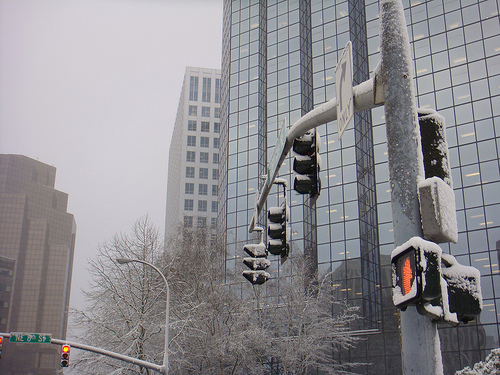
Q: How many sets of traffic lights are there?
A: There are three sets of traffic lights.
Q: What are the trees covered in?
A: The trees are covered in snow.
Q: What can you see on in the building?
A: The lights are on in the building.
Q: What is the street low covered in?
A: The Street light is covered in snow.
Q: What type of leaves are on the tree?
A: There are no leaves on the tree.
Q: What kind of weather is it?
A: Snowy.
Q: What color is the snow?
A: White.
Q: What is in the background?
A: Buildings.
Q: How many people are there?
A: None.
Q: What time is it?
A: Afternoon.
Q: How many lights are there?
A: More than one.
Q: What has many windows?
A: The building.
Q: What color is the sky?
A: Gray.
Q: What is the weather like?
A: Cold.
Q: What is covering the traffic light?
A: Snow.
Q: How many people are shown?
A: None.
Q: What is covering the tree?
A: Snow.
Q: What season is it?
A: Winter.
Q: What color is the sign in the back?
A: Green and white.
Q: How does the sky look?
A: Gray.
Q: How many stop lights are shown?
A: Four.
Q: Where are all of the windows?
A: In the back on the buildings.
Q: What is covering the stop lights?
A: Snow.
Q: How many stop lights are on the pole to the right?
A: Three.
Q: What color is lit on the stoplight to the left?
A: Red.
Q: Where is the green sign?
A: On the street pole.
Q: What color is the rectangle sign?
A: Green.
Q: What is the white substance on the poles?
A: Snow.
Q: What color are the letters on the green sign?
A: White.